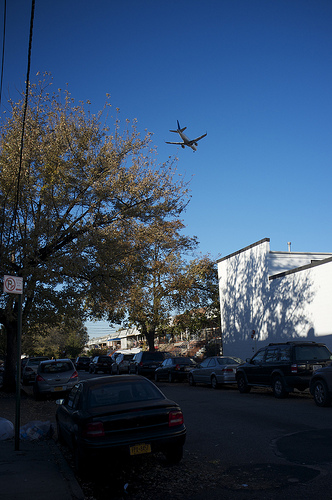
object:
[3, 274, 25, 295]
sign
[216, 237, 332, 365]
building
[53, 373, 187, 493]
car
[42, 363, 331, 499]
street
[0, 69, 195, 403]
tree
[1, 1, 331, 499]
city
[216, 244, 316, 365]
shadow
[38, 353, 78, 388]
cars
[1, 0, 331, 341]
sky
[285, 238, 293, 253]
smokestack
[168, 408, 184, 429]
tail light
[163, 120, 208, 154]
airplane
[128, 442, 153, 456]
license plate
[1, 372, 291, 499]
leaves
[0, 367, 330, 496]
ground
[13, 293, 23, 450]
pole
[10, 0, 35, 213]
wire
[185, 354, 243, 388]
car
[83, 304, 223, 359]
building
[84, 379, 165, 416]
windows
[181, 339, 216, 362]
steps